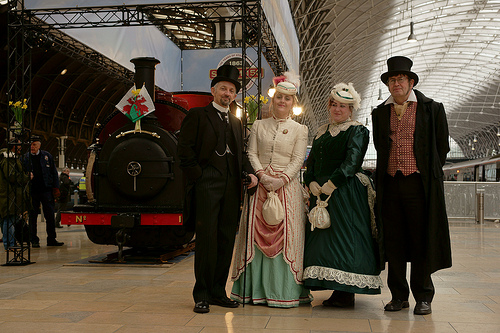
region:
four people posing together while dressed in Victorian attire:
[181, 53, 453, 319]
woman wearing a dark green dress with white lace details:
[306, 118, 381, 294]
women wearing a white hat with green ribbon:
[329, 81, 364, 111]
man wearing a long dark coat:
[372, 87, 452, 272]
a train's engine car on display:
[57, 54, 217, 269]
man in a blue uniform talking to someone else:
[3, 135, 65, 251]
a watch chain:
[212, 141, 231, 161]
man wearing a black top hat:
[210, 63, 242, 111]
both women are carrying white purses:
[257, 168, 337, 230]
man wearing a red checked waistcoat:
[384, 98, 416, 178]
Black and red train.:
[72, 44, 192, 261]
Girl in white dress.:
[247, 64, 310, 321]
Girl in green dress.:
[307, 67, 387, 312]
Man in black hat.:
[175, 55, 257, 317]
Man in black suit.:
[174, 55, 260, 315]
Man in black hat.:
[367, 44, 457, 315]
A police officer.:
[16, 126, 76, 261]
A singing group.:
[178, 47, 449, 319]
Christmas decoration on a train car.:
[108, 70, 158, 126]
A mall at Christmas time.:
[86, 0, 496, 328]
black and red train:
[61, 56, 214, 261]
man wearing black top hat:
[176, 63, 246, 315]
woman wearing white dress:
[235, 70, 307, 306]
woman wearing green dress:
[306, 82, 381, 307]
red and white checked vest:
[387, 102, 416, 177]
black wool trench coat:
[369, 90, 453, 270]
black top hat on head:
[379, 55, 420, 82]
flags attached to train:
[115, 84, 157, 123]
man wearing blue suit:
[22, 134, 62, 249]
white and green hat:
[333, 83, 362, 107]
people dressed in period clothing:
[168, 30, 460, 235]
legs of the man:
[178, 215, 248, 312]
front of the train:
[66, 49, 191, 240]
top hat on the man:
[213, 58, 247, 95]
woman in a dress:
[231, 63, 330, 277]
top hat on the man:
[374, 49, 431, 84]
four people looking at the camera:
[160, 48, 464, 241]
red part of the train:
[49, 189, 181, 246]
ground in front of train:
[51, 265, 131, 325]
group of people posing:
[165, 57, 447, 319]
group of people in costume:
[164, 42, 449, 317]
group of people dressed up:
[163, 51, 459, 324]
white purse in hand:
[260, 188, 284, 236]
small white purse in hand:
[312, 200, 329, 222]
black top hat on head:
[203, 60, 245, 105]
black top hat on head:
[371, 53, 421, 99]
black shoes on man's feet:
[197, 288, 242, 316]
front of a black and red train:
[37, 50, 197, 265]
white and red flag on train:
[117, 77, 157, 134]